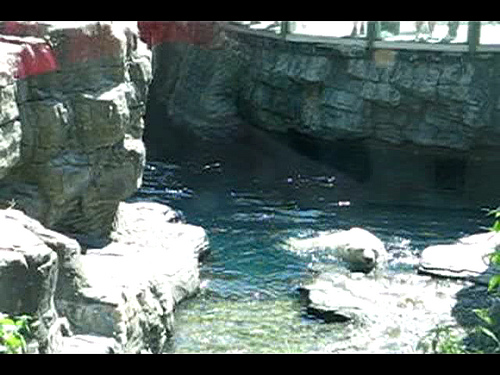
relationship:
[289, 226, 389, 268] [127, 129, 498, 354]
bear in river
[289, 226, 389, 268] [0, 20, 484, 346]
bear at zoo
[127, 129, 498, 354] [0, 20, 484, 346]
river at zoo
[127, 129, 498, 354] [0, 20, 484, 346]
river in a zoo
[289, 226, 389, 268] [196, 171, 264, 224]
bear in water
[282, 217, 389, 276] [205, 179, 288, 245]
bear in water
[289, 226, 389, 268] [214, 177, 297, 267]
bear in water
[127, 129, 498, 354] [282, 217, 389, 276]
river in bear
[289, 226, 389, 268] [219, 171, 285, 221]
bear in water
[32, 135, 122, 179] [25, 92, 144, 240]
cracks in rock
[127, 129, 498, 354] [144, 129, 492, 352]
river in river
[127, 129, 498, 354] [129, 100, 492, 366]
river in river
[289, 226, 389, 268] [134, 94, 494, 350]
bear in water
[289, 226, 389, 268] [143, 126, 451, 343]
bear in water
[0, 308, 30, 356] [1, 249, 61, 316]
foliage next to rock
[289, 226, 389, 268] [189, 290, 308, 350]
bear in water